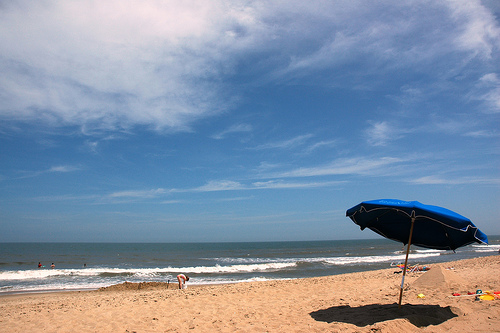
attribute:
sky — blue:
[8, 26, 188, 138]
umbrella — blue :
[345, 195, 488, 324]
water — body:
[46, 247, 136, 267]